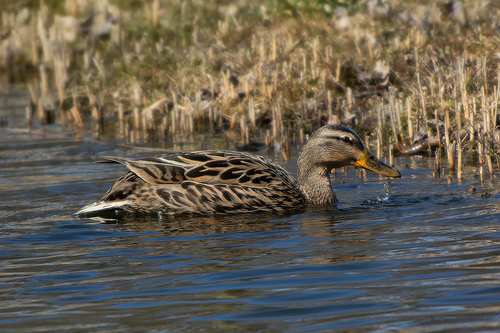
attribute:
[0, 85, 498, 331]
water — rippled , blue 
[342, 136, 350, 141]
eye — black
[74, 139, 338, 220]
feathers — black outline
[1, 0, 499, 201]
grass reeds — grass 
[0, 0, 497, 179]
grass — brown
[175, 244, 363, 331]
water — swimming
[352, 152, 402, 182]
bill — orange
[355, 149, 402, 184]
peak — black, yellow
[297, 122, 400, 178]
head — gray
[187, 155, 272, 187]
spots — black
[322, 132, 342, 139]
stripe — black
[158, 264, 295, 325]
rippled water — blue , rippled 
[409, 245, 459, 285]
water — rippled , blue 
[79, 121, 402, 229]
duck — brown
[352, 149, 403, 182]
beak — Orange  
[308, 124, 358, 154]
stripes — black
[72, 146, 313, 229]
body — brown